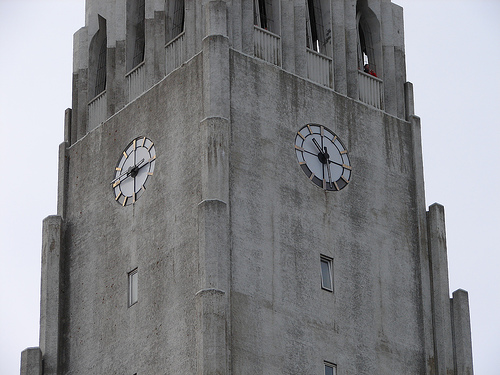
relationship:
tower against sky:
[38, 1, 466, 373] [0, 2, 78, 307]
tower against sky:
[38, 1, 466, 373] [409, 3, 499, 262]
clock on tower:
[292, 121, 353, 193] [79, 40, 419, 360]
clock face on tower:
[293, 120, 350, 194] [14, 1, 477, 374]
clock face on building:
[107, 133, 157, 208] [49, 11, 412, 299]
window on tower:
[125, 265, 141, 310] [14, 1, 477, 374]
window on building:
[318, 251, 337, 295] [70, 5, 438, 374]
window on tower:
[318, 251, 337, 295] [14, 1, 477, 374]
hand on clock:
[132, 157, 144, 170] [89, 129, 178, 217]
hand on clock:
[324, 155, 334, 191] [292, 121, 353, 193]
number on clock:
[297, 111, 327, 151] [296, 116, 400, 214]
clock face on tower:
[291, 120, 354, 194] [38, 1, 466, 373]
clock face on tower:
[106, 131, 159, 207] [38, 1, 466, 373]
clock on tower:
[289, 118, 356, 195] [14, 1, 477, 374]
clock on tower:
[110, 132, 160, 204] [14, 1, 477, 374]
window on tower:
[318, 251, 337, 295] [38, 1, 466, 373]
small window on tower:
[322, 359, 337, 374] [14, 1, 477, 374]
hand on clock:
[316, 135, 332, 195] [276, 108, 351, 203]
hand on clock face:
[307, 135, 333, 158] [287, 117, 383, 205]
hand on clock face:
[131, 155, 147, 170] [98, 134, 165, 207]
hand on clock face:
[108, 169, 127, 187] [107, 134, 167, 206]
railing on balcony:
[160, 34, 190, 61] [140, 19, 242, 101]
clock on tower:
[109, 132, 160, 209] [50, 19, 459, 367]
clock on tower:
[109, 132, 160, 209] [38, 1, 466, 373]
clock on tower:
[292, 121, 353, 193] [38, 1, 466, 373]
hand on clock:
[324, 155, 334, 191] [287, 97, 393, 219]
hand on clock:
[108, 171, 129, 188] [106, 138, 161, 210]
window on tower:
[125, 265, 138, 308] [38, 1, 466, 373]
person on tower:
[363, 62, 378, 77] [38, 1, 466, 373]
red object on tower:
[364, 61, 377, 78] [38, 1, 466, 373]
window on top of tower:
[354, 6, 379, 78] [38, 1, 466, 373]